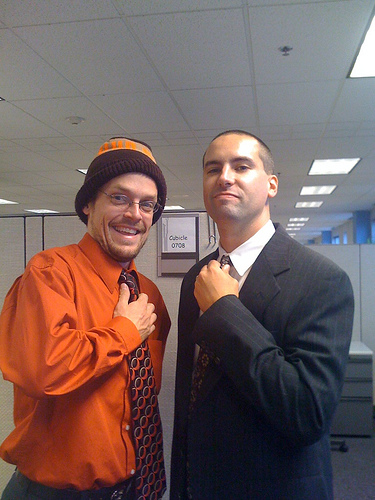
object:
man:
[0, 138, 172, 499]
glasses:
[96, 188, 165, 214]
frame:
[97, 187, 164, 211]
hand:
[113, 282, 156, 343]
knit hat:
[76, 134, 168, 226]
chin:
[108, 240, 142, 258]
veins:
[135, 324, 149, 333]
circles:
[145, 404, 153, 418]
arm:
[0, 268, 126, 400]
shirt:
[0, 231, 171, 491]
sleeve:
[195, 272, 354, 441]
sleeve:
[0, 265, 143, 398]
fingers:
[118, 283, 131, 306]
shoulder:
[24, 241, 90, 300]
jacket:
[169, 223, 354, 500]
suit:
[171, 221, 354, 499]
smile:
[110, 223, 143, 241]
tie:
[117, 269, 167, 500]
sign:
[156, 214, 199, 278]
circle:
[142, 435, 152, 449]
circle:
[134, 346, 144, 359]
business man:
[170, 130, 354, 500]